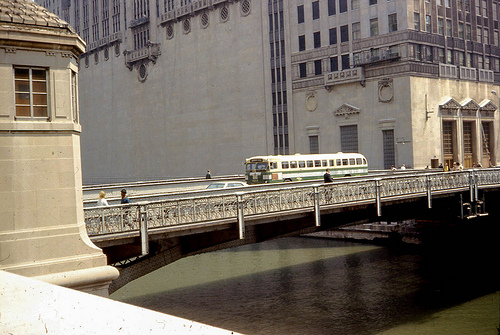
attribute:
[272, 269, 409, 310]
water — green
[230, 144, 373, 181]
bus — green, white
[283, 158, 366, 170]
windows — large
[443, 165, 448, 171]
shirt — yellow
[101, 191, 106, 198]
hair — laptop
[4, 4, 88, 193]
building — large, white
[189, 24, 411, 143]
structure — stone, circular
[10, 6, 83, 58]
structures — triangular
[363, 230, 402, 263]
shadow — black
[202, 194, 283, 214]
side rails — decorative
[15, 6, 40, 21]
roof — black